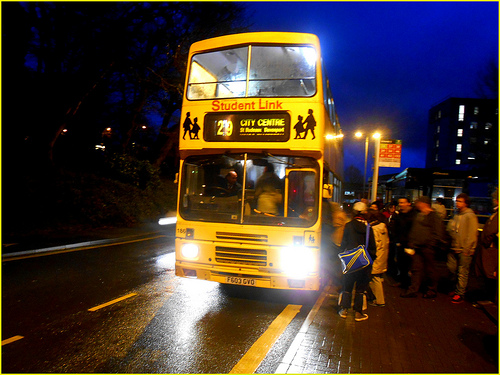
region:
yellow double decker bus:
[171, 30, 343, 304]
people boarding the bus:
[318, 186, 498, 322]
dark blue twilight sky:
[236, 1, 498, 183]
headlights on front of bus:
[178, 239, 318, 281]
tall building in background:
[423, 95, 498, 177]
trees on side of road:
[0, 1, 253, 225]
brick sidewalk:
[274, 298, 498, 372]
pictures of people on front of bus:
[181, 105, 321, 144]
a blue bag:
[336, 222, 373, 277]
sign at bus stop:
[371, 134, 403, 203]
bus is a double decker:
[177, 32, 334, 294]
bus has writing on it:
[200, 99, 285, 109]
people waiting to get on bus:
[320, 192, 476, 332]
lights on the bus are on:
[178, 237, 315, 280]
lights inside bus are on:
[208, 48, 318, 94]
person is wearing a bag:
[337, 241, 371, 276]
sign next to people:
[367, 129, 405, 196]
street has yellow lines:
[90, 291, 292, 363]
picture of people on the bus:
[294, 106, 316, 143]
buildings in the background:
[427, 93, 488, 197]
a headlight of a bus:
[175, 245, 200, 261]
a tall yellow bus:
[167, 31, 347, 298]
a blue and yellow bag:
[334, 220, 376, 275]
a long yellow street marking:
[78, 282, 138, 316]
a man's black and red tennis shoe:
[447, 292, 463, 302]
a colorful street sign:
[364, 132, 402, 213]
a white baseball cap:
[351, 196, 365, 213]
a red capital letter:
[209, 94, 224, 111]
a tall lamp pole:
[352, 123, 382, 191]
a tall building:
[425, 96, 495, 181]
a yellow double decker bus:
[165, 35, 345, 312]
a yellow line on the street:
[246, 312, 274, 364]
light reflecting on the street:
[158, 287, 218, 339]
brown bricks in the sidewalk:
[326, 332, 373, 370]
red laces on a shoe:
[449, 295, 466, 302]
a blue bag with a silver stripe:
[334, 248, 383, 273]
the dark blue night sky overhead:
[349, 15, 445, 85]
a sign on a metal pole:
[369, 130, 397, 200]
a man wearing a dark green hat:
[410, 190, 437, 292]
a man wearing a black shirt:
[392, 195, 414, 235]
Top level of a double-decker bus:
[164, 32, 352, 157]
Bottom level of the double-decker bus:
[164, 150, 335, 299]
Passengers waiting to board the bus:
[329, 185, 484, 317]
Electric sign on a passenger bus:
[200, 108, 298, 148]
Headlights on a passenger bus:
[180, 240, 317, 276]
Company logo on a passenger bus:
[210, 98, 287, 113]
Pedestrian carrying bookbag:
[332, 199, 374, 329]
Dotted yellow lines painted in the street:
[75, 284, 150, 317]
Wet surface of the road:
[155, 291, 225, 366]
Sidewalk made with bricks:
[328, 321, 431, 373]